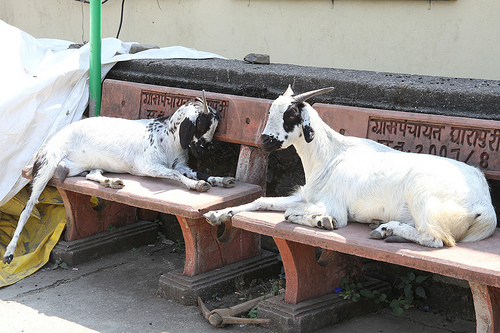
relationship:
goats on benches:
[86, 84, 446, 237] [120, 88, 404, 291]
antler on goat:
[285, 80, 343, 114] [245, 76, 444, 297]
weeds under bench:
[335, 264, 429, 330] [185, 185, 471, 307]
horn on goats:
[286, 69, 354, 122] [234, 79, 474, 272]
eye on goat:
[275, 90, 313, 128] [244, 92, 462, 293]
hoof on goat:
[192, 196, 257, 226] [231, 101, 483, 294]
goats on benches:
[46, 93, 411, 250] [46, 106, 357, 286]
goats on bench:
[65, 82, 478, 255] [139, 68, 412, 319]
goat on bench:
[0, 89, 237, 272] [18, 71, 499, 329]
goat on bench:
[201, 80, 498, 252] [18, 71, 499, 329]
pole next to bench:
[86, 0, 107, 119] [60, 75, 497, 331]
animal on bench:
[196, 81, 499, 251] [18, 71, 499, 329]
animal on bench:
[0, 91, 234, 271] [18, 71, 499, 329]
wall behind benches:
[3, 0, 497, 82] [16, 74, 496, 330]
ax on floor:
[183, 288, 271, 330] [8, 228, 478, 330]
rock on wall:
[237, 47, 274, 67] [94, 43, 499, 120]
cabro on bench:
[0, 85, 240, 265] [18, 71, 499, 329]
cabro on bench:
[198, 77, 499, 257] [18, 71, 499, 329]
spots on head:
[174, 117, 195, 150] [159, 90, 228, 160]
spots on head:
[192, 107, 212, 137] [159, 90, 228, 160]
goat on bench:
[253, 95, 477, 265] [330, 232, 369, 259]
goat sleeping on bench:
[32, 103, 221, 190] [153, 190, 205, 253]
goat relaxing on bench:
[256, 90, 465, 245] [332, 256, 475, 303]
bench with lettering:
[371, 110, 461, 142] [369, 112, 477, 137]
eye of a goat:
[283, 102, 309, 132] [260, 88, 480, 244]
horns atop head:
[284, 81, 328, 105] [263, 100, 308, 147]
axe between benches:
[183, 279, 272, 331] [187, 210, 277, 300]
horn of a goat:
[299, 86, 332, 96] [239, 66, 479, 234]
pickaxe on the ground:
[184, 284, 265, 322] [143, 312, 175, 330]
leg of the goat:
[197, 186, 280, 234] [204, 85, 477, 254]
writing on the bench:
[385, 124, 485, 146] [319, 235, 375, 261]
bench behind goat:
[319, 235, 375, 261] [204, 85, 477, 254]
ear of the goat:
[308, 119, 320, 143] [204, 95, 479, 248]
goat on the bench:
[50, 91, 215, 189] [125, 189, 202, 198]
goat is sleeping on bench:
[28, 97, 233, 171] [143, 177, 166, 201]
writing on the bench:
[373, 119, 444, 151] [346, 221, 370, 250]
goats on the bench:
[40, 86, 477, 246] [33, 62, 483, 295]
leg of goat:
[10, 161, 42, 271] [20, 118, 216, 201]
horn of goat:
[289, 74, 337, 109] [260, 88, 480, 244]